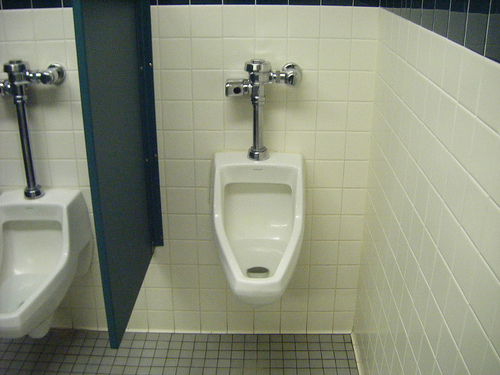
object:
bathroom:
[0, 0, 499, 375]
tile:
[157, 5, 192, 39]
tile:
[447, 0, 470, 47]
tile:
[319, 342, 333, 350]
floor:
[0, 327, 361, 375]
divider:
[69, 0, 167, 349]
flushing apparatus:
[225, 79, 253, 97]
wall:
[151, 0, 380, 334]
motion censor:
[233, 86, 242, 95]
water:
[241, 256, 276, 279]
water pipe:
[253, 105, 265, 148]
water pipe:
[15, 104, 38, 190]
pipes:
[247, 95, 270, 160]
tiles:
[351, 6, 381, 40]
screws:
[148, 62, 152, 66]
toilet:
[213, 149, 307, 307]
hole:
[246, 266, 270, 278]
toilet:
[0, 188, 96, 340]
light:
[254, 96, 258, 99]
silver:
[243, 58, 272, 162]